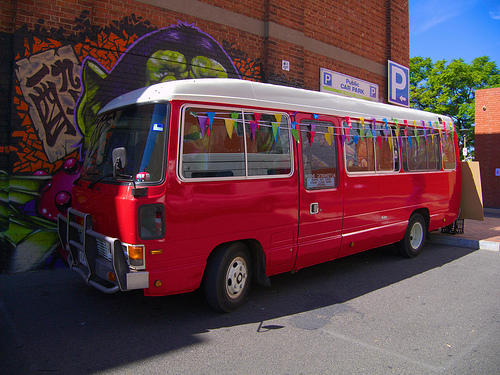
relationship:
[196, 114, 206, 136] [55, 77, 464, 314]
flag on bus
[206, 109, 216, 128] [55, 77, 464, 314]
flag on bus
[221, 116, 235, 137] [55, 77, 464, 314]
flag on bus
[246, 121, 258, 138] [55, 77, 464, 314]
flag on bus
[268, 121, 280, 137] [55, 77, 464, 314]
flag on bus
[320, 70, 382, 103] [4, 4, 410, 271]
sign on building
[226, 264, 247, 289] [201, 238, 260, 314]
rim inside tire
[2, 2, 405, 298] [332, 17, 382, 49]
building made out of bricks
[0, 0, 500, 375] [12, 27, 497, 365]
picture taken outdoors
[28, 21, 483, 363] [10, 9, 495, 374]
picture taken day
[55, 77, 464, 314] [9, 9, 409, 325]
bus front building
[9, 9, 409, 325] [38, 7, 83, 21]
building made of brick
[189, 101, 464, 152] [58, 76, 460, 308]
flags in bus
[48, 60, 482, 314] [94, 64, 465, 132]
bus has top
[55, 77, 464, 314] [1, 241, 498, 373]
bus above road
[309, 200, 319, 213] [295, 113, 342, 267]
handle on door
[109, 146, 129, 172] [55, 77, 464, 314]
mirror on bus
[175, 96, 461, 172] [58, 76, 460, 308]
flags hung on bus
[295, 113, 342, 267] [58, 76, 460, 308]
door on side of bus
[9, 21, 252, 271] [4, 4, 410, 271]
graffiti on wall of a building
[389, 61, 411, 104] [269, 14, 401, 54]
sign for parking area on wall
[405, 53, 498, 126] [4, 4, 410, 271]
tree behind building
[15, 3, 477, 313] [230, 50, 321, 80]
combi parked in front of building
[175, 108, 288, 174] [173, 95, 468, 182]
windows with white frame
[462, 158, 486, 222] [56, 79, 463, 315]
brown board leaning against combi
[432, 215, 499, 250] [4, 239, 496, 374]
sidewalk behind parking area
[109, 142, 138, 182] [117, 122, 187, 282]
mirror hanging off side